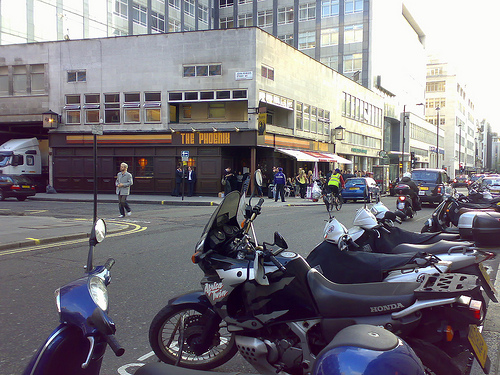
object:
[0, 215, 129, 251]
curb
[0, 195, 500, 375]
road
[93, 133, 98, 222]
post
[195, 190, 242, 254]
windshield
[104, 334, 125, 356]
handle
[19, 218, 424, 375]
bike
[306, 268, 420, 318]
seat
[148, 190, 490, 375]
bike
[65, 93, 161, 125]
windows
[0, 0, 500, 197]
building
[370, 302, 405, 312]
brand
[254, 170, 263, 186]
mirror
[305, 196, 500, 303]
bikes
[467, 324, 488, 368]
plate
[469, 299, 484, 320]
reflector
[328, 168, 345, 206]
people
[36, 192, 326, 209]
sidewalk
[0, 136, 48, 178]
truck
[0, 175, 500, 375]
street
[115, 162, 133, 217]
man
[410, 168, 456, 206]
car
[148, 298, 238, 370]
tire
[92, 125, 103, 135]
sign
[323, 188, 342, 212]
bicycle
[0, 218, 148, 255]
line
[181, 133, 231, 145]
letters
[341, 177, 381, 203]
car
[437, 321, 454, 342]
light